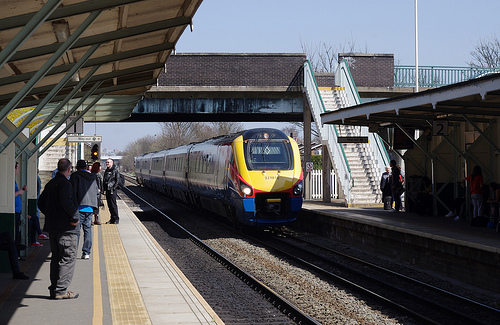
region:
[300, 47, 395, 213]
A flight of stairs.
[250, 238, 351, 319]
Gravel in-between the tracks.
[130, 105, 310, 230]
A train.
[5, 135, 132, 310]
People waiting for the train.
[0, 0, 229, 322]
The station platform.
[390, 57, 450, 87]
A guardrail.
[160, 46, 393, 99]
A wall is on either side of the stairs.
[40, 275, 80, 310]
The man is wearing sneakers.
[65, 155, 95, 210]
The man is wearing a jacket.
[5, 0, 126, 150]
Support beams for the roof.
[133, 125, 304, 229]
yellow, blue, and white train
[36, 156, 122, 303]
people standing in platform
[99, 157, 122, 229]
man wearing black pants and black jacket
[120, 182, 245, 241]
train's shadow on the ground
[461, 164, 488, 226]
woman with red shirt and dark shoes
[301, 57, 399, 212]
stairs connecting to platform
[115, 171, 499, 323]
train rails on the ground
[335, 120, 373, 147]
sign hanging from the ceiling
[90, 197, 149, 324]
yellow line across the platform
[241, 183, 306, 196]
headlight in front of train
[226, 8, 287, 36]
blue sky above train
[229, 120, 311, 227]
front of the train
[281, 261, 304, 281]
rocks next to the track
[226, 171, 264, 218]
light on the train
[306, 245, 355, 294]
track below the train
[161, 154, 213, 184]
side of the train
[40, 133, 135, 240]
people on the sidewalk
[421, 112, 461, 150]
the number 2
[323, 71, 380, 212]
stairs next to the train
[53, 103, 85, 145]
the number 1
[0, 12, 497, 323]
An outside train station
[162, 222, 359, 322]
Empty train tracks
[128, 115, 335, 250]
A train stopping at a train station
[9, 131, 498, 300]
People waiting on trains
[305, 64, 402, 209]
White stairs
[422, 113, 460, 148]
A number two sign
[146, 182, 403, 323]
Gravel between the tracks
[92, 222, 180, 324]
Yellow lines on the sidewalk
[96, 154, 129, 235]
A person in a black leather jacket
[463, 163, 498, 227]
A woman in a red top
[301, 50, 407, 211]
White stairs behind train platform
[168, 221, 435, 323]
Two sets of train tracks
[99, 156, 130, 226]
Man in black holding black backpack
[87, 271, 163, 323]
Yellow paint near platform edge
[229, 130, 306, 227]
Yellow red and blue train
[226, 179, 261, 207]
Lighted train headlight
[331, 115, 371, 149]
Sign hanging from platform roof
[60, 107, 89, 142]
Black and white sign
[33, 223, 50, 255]
Person's red shoes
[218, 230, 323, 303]
Grey gravel between train tracks